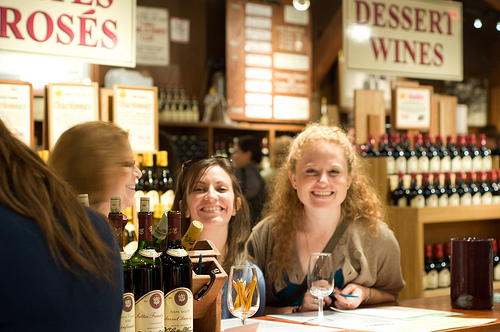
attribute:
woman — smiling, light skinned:
[281, 132, 377, 301]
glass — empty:
[301, 255, 337, 324]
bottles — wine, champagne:
[387, 138, 487, 197]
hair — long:
[269, 160, 295, 254]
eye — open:
[331, 164, 344, 177]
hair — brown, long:
[6, 143, 63, 225]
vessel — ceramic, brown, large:
[448, 232, 497, 297]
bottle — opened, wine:
[161, 201, 196, 327]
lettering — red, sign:
[5, 7, 118, 45]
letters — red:
[378, 9, 437, 69]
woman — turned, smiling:
[59, 115, 139, 218]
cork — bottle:
[140, 191, 151, 211]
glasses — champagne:
[224, 248, 346, 320]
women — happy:
[60, 125, 384, 293]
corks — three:
[75, 193, 153, 210]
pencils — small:
[240, 275, 256, 313]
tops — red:
[417, 134, 444, 142]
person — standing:
[236, 139, 264, 240]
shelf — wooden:
[161, 107, 325, 133]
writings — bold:
[7, 2, 142, 56]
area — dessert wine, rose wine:
[304, 7, 500, 120]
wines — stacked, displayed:
[363, 127, 499, 254]